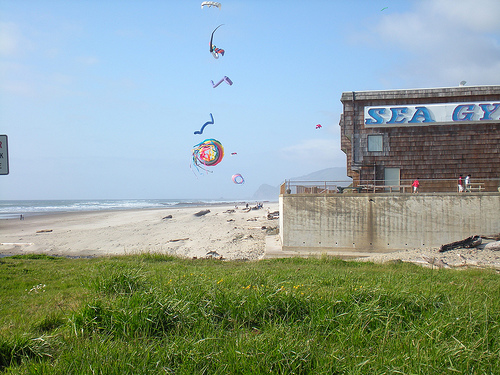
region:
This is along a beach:
[35, 26, 472, 347]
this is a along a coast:
[45, 82, 302, 327]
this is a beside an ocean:
[1, 167, 312, 372]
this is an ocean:
[11, 193, 123, 231]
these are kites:
[172, 42, 279, 236]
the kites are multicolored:
[156, 43, 298, 248]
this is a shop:
[330, 80, 499, 187]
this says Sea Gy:
[340, 94, 491, 151]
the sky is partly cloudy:
[40, 42, 187, 188]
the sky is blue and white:
[26, 28, 166, 177]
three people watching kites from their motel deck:
[409, 173, 483, 194]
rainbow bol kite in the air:
[192, 138, 224, 166]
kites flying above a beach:
[189, 1, 322, 183]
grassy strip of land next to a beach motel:
[1, 251, 496, 373]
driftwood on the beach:
[163, 201, 278, 246]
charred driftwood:
[440, 235, 482, 251]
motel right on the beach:
[282, 87, 499, 251]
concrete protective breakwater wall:
[279, 194, 499, 250]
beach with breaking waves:
[0, 197, 280, 257]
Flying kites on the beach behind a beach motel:
[5, 3, 495, 370]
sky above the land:
[63, 43, 154, 110]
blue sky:
[84, 41, 181, 136]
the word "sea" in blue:
[350, 96, 443, 141]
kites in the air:
[148, 16, 277, 200]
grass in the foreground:
[123, 278, 249, 373]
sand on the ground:
[151, 209, 218, 244]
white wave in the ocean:
[57, 190, 111, 226]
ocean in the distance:
[28, 190, 75, 210]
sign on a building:
[346, 98, 462, 139]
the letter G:
[446, 93, 481, 135]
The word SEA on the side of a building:
[366, 105, 436, 127]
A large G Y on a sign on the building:
[449, 100, 499, 124]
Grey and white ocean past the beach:
[1, 197, 173, 218]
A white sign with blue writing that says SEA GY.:
[361, 103, 499, 125]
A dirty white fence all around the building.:
[276, 180, 498, 251]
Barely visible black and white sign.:
[0, 132, 12, 176]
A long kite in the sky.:
[190, 3, 234, 175]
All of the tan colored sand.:
[2, 200, 280, 260]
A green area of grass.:
[1, 256, 498, 373]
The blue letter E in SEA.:
[384, 106, 409, 127]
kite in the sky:
[180, 133, 228, 182]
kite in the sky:
[226, 168, 248, 188]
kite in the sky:
[310, 117, 325, 134]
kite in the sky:
[184, 108, 219, 140]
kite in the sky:
[225, 146, 240, 158]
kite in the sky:
[207, 70, 235, 92]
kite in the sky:
[199, 18, 231, 64]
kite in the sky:
[199, 0, 224, 8]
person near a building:
[405, 170, 420, 195]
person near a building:
[460, 168, 479, 195]